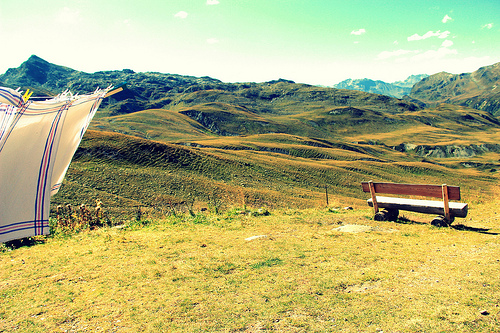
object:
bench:
[361, 180, 467, 227]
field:
[0, 201, 499, 331]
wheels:
[371, 204, 397, 221]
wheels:
[431, 212, 454, 227]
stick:
[369, 181, 379, 217]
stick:
[442, 183, 451, 223]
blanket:
[1, 86, 106, 245]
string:
[28, 95, 57, 99]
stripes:
[1, 219, 51, 234]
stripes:
[1, 89, 24, 107]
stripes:
[21, 105, 68, 115]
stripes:
[34, 99, 67, 232]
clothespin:
[22, 86, 35, 105]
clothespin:
[99, 86, 123, 101]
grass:
[0, 209, 498, 331]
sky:
[1, 1, 497, 68]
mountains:
[2, 53, 499, 111]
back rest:
[360, 180, 460, 199]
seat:
[367, 196, 468, 218]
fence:
[53, 201, 199, 231]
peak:
[24, 55, 49, 70]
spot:
[329, 223, 372, 237]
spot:
[242, 234, 267, 242]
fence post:
[323, 184, 329, 205]